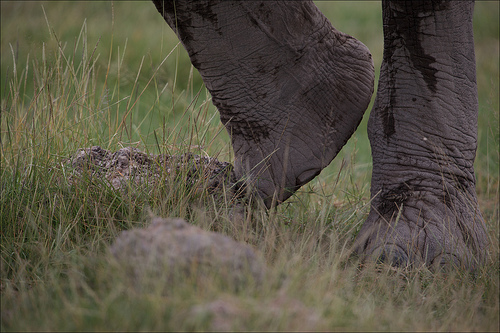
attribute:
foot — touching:
[197, 40, 397, 217]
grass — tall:
[23, 88, 213, 178]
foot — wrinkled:
[379, 92, 490, 233]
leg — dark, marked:
[357, 2, 466, 138]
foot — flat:
[265, 52, 383, 231]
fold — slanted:
[371, 39, 499, 208]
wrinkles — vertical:
[249, 51, 365, 128]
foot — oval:
[246, 158, 357, 210]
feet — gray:
[164, 21, 499, 252]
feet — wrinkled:
[216, 25, 494, 275]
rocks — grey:
[72, 133, 230, 327]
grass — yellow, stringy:
[20, 52, 246, 322]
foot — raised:
[177, 21, 474, 263]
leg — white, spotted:
[394, 101, 461, 168]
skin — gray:
[390, 100, 462, 210]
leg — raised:
[152, 0, 382, 224]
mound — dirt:
[57, 140, 250, 227]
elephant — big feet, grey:
[151, 1, 484, 272]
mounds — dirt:
[92, 185, 275, 311]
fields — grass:
[16, 64, 387, 315]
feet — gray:
[219, 22, 384, 222]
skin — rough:
[168, 4, 382, 229]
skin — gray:
[222, 36, 318, 117]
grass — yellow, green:
[32, 31, 150, 141]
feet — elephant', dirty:
[232, 27, 476, 283]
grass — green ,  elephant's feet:
[14, 22, 171, 135]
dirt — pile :
[123, 190, 297, 297]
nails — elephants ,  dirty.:
[213, 153, 299, 205]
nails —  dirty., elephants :
[242, 150, 322, 230]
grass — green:
[24, 39, 123, 71]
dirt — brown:
[75, 203, 303, 311]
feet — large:
[159, 4, 380, 220]